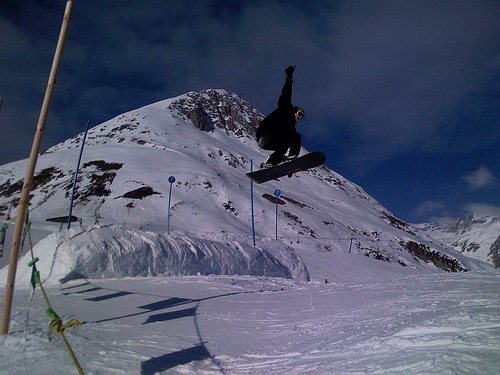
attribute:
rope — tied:
[34, 269, 58, 314]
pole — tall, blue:
[32, 57, 69, 89]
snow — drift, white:
[281, 302, 321, 342]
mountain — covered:
[149, 83, 258, 182]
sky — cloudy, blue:
[160, 12, 290, 77]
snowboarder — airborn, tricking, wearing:
[257, 57, 346, 168]